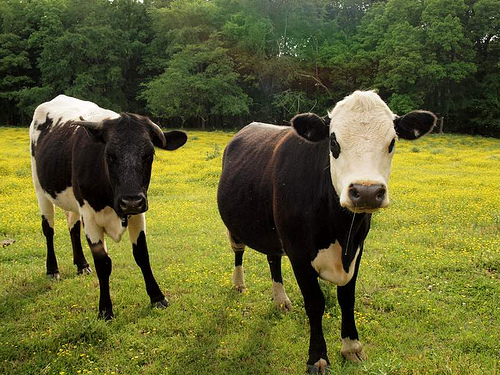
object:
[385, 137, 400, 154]
eye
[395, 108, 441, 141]
ear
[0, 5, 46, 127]
tree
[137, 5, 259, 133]
tree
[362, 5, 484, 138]
tree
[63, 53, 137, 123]
tree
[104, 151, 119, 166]
eye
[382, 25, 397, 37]
leaves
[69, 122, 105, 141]
horn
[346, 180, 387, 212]
nose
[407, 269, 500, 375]
green grass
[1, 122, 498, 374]
grass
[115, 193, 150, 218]
muzzle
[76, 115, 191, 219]
head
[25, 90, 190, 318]
cow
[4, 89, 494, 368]
field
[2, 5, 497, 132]
area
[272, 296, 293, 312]
white hoof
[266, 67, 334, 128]
trees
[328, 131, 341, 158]
eye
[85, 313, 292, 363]
green grass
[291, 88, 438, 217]
head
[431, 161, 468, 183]
patch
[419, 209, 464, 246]
patch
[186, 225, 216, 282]
patch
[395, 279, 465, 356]
patch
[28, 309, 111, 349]
patch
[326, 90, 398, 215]
face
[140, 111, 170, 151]
horn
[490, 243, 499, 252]
flowers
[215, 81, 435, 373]
cow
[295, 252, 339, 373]
legs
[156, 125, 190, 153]
ear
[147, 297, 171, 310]
hoof